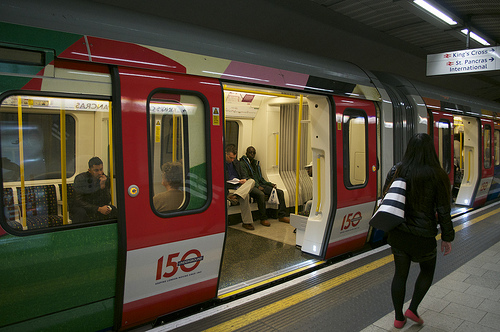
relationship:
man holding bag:
[239, 146, 291, 224] [269, 187, 280, 205]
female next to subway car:
[369, 133, 456, 329] [0, 0, 500, 332]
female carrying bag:
[369, 133, 456, 329] [374, 165, 407, 241]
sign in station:
[425, 46, 500, 77] [359, 14, 484, 329]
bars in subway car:
[294, 94, 303, 215] [4, 16, 404, 330]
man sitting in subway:
[239, 146, 291, 227] [1, 0, 496, 328]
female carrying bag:
[369, 133, 456, 329] [367, 163, 408, 229]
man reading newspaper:
[227, 151, 255, 229] [228, 175, 239, 185]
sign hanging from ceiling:
[420, 43, 497, 79] [108, 1, 498, 90]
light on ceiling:
[417, 0, 459, 27] [309, 0, 499, 89]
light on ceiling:
[459, 24, 491, 47] [309, 0, 499, 89]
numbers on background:
[161, 257, 198, 276] [126, 243, 222, 292]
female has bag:
[369, 133, 456, 329] [365, 163, 412, 229]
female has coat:
[369, 133, 456, 329] [374, 157, 459, 254]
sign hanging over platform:
[425, 46, 500, 77] [402, 190, 481, 318]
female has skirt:
[369, 133, 456, 329] [387, 226, 442, 266]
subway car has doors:
[0, 0, 500, 332] [112, 63, 377, 325]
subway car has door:
[0, 0, 500, 332] [427, 108, 495, 208]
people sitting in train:
[84, 145, 274, 219] [21, 27, 487, 323]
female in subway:
[369, 133, 456, 329] [1, 0, 496, 328]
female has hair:
[369, 133, 456, 329] [394, 131, 442, 191]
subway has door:
[1, 0, 496, 328] [114, 75, 227, 307]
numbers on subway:
[155, 249, 203, 280] [222, 87, 325, 299]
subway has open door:
[1, 0, 496, 328] [215, 82, 332, 301]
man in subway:
[218, 143, 256, 230] [1, 0, 496, 328]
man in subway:
[239, 146, 291, 227] [1, 0, 496, 328]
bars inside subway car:
[287, 94, 307, 244] [0, 0, 500, 332]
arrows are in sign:
[484, 45, 499, 54] [424, 41, 499, 77]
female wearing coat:
[369, 133, 456, 329] [382, 161, 456, 256]